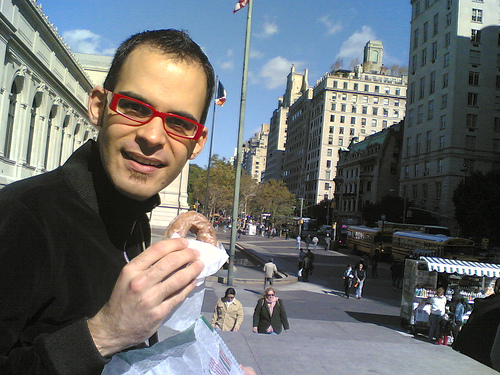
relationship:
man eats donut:
[1, 25, 211, 374] [168, 206, 224, 244]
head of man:
[95, 27, 217, 209] [1, 25, 211, 374]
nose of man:
[138, 114, 167, 146] [1, 25, 211, 374]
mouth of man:
[118, 146, 178, 169] [1, 25, 211, 374]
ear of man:
[85, 86, 111, 129] [1, 25, 211, 374]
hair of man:
[140, 28, 220, 64] [1, 25, 211, 374]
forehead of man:
[128, 53, 218, 115] [1, 25, 211, 374]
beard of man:
[120, 169, 158, 202] [1, 25, 211, 374]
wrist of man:
[87, 299, 126, 355] [1, 25, 211, 374]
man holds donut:
[1, 25, 211, 374] [168, 206, 224, 244]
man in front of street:
[1, 25, 211, 374] [232, 227, 394, 293]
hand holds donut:
[106, 239, 205, 341] [168, 206, 224, 244]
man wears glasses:
[1, 25, 211, 374] [99, 89, 214, 143]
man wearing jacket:
[1, 25, 211, 374] [2, 141, 164, 374]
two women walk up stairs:
[208, 282, 292, 333] [220, 337, 451, 369]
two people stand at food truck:
[422, 281, 469, 340] [398, 252, 493, 331]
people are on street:
[295, 246, 369, 294] [232, 227, 394, 293]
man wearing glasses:
[1, 25, 211, 374] [99, 89, 214, 143]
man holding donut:
[1, 25, 211, 374] [168, 206, 224, 244]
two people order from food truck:
[422, 281, 469, 340] [398, 252, 493, 331]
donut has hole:
[168, 206, 224, 244] [187, 223, 204, 243]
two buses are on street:
[344, 222, 482, 258] [232, 227, 394, 293]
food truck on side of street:
[398, 252, 493, 331] [232, 227, 394, 293]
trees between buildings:
[187, 159, 292, 231] [242, 41, 410, 185]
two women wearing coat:
[208, 282, 292, 333] [209, 299, 244, 325]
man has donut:
[1, 25, 211, 374] [168, 206, 224, 244]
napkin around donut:
[167, 240, 232, 329] [168, 206, 224, 244]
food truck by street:
[398, 252, 493, 331] [232, 227, 394, 293]